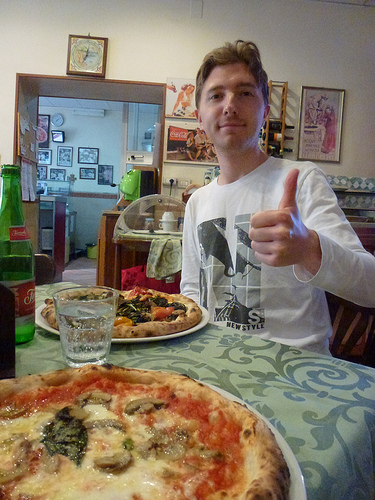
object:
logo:
[197, 217, 265, 325]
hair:
[194, 39, 269, 109]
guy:
[180, 38, 375, 354]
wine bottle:
[262, 132, 294, 142]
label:
[274, 133, 282, 142]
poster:
[164, 76, 219, 165]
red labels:
[0, 276, 36, 326]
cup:
[52, 284, 119, 368]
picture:
[66, 32, 108, 79]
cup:
[159, 212, 178, 222]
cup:
[159, 222, 176, 231]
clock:
[50, 113, 64, 127]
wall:
[69, 120, 114, 146]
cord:
[169, 179, 174, 196]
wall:
[1, 1, 375, 187]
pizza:
[40, 286, 202, 338]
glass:
[56, 275, 127, 369]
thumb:
[278, 169, 300, 210]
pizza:
[0, 363, 292, 500]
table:
[15, 281, 375, 499]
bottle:
[0, 162, 35, 344]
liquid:
[56, 305, 116, 360]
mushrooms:
[91, 392, 188, 471]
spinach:
[39, 406, 88, 467]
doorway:
[13, 73, 167, 194]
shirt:
[179, 156, 375, 356]